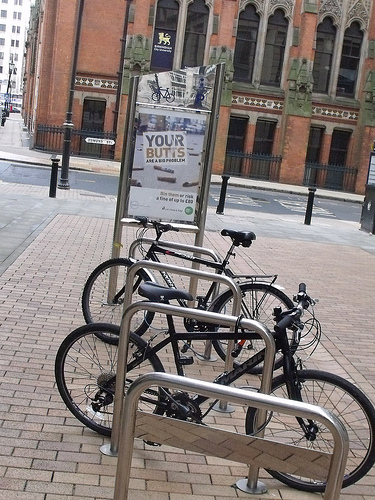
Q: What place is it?
A: It is a sidewalk.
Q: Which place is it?
A: It is a sidewalk.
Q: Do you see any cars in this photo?
A: No, there are no cars.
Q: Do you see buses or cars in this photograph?
A: No, there are no cars or buses.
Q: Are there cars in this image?
A: No, there are no cars.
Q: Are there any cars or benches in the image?
A: No, there are no cars or benches.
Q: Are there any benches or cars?
A: No, there are no cars or benches.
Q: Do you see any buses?
A: No, there are no buses.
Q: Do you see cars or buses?
A: No, there are no buses or cars.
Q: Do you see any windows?
A: Yes, there is a window.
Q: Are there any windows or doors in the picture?
A: Yes, there is a window.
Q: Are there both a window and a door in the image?
A: Yes, there are both a window and a door.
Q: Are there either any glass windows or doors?
A: Yes, there is a glass window.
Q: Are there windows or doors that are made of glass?
A: Yes, the window is made of glass.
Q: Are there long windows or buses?
A: Yes, there is a long window.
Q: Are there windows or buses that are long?
A: Yes, the window is long.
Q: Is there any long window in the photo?
A: Yes, there is a long window.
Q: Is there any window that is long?
A: Yes, there is a window that is long.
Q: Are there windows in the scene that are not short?
A: Yes, there is a long window.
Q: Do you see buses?
A: No, there are no buses.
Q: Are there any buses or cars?
A: No, there are no buses or cars.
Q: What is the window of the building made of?
A: The window is made of glass.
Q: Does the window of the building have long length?
A: Yes, the window is long.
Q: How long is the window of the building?
A: The window is long.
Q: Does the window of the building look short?
A: No, the window is long.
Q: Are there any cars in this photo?
A: No, there are no cars.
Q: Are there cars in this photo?
A: No, there are no cars.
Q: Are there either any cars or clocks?
A: No, there are no cars or clocks.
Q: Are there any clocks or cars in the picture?
A: No, there are no cars or clocks.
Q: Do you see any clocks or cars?
A: No, there are no cars or clocks.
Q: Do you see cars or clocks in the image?
A: No, there are no cars or clocks.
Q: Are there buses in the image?
A: No, there are no buses.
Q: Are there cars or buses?
A: No, there are no buses or cars.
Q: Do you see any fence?
A: Yes, there is a fence.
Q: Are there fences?
A: Yes, there is a fence.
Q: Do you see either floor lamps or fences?
A: Yes, there is a fence.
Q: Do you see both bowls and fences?
A: No, there is a fence but no bowls.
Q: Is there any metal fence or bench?
A: Yes, there is a metal fence.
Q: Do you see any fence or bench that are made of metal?
A: Yes, the fence is made of metal.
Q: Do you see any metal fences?
A: Yes, there is a metal fence.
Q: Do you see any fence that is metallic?
A: Yes, there is a fence that is metallic.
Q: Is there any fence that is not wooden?
A: Yes, there is a metallic fence.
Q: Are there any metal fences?
A: Yes, there is a fence that is made of metal.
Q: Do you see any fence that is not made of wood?
A: Yes, there is a fence that is made of metal.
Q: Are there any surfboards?
A: No, there are no surfboards.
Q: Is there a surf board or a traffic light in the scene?
A: No, there are no surfboards or traffic lights.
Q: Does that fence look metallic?
A: Yes, the fence is metallic.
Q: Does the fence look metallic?
A: Yes, the fence is metallic.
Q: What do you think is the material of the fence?
A: The fence is made of metal.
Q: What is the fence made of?
A: The fence is made of metal.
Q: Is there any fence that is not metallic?
A: No, there is a fence but it is metallic.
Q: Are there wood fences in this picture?
A: No, there is a fence but it is made of metal.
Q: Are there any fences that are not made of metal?
A: No, there is a fence but it is made of metal.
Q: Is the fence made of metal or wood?
A: The fence is made of metal.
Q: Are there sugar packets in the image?
A: No, there are no sugar packets.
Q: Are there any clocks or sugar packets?
A: No, there are no sugar packets or clocks.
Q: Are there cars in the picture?
A: No, there are no cars.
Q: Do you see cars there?
A: No, there are no cars.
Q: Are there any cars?
A: No, there are no cars.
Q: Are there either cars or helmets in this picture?
A: No, there are no cars or helmets.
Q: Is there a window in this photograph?
A: Yes, there is a window.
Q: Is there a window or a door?
A: Yes, there is a window.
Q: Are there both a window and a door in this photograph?
A: Yes, there are both a window and a door.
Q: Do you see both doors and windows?
A: Yes, there are both a window and a door.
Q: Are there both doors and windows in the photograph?
A: Yes, there are both a window and a door.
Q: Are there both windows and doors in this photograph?
A: Yes, there are both a window and a door.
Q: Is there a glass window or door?
A: Yes, there is a glass window.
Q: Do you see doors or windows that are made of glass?
A: Yes, the window is made of glass.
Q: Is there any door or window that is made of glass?
A: Yes, the window is made of glass.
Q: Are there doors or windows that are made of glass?
A: Yes, the window is made of glass.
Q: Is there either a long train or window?
A: Yes, there is a long window.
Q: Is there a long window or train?
A: Yes, there is a long window.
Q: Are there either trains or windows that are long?
A: Yes, the window is long.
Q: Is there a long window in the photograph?
A: Yes, there is a long window.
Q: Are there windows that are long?
A: Yes, there is a window that is long.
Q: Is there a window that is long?
A: Yes, there is a window that is long.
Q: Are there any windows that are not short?
A: Yes, there is a long window.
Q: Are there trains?
A: No, there are no trains.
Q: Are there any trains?
A: No, there are no trains.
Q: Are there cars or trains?
A: No, there are no trains or cars.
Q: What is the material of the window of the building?
A: The window is made of glass.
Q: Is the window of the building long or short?
A: The window is long.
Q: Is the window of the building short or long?
A: The window is long.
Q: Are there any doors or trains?
A: Yes, there is a door.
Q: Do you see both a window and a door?
A: Yes, there are both a door and a window.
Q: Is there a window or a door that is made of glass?
A: Yes, the door is made of glass.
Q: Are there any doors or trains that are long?
A: Yes, the door is long.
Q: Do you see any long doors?
A: Yes, there is a long door.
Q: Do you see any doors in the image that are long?
A: Yes, there is a door that is long.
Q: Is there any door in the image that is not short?
A: Yes, there is a long door.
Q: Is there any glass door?
A: Yes, there is a door that is made of glass.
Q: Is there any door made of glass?
A: Yes, there is a door that is made of glass.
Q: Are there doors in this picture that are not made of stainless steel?
A: Yes, there is a door that is made of glass.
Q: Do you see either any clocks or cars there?
A: No, there are no cars or clocks.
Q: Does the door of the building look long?
A: Yes, the door is long.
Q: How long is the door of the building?
A: The door is long.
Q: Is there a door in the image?
A: Yes, there is a door.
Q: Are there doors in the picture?
A: Yes, there is a door.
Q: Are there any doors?
A: Yes, there is a door.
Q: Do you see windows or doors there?
A: Yes, there is a door.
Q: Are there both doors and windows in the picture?
A: Yes, there are both a door and a window.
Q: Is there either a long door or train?
A: Yes, there is a long door.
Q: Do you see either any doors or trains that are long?
A: Yes, the door is long.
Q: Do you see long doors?
A: Yes, there is a long door.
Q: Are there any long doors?
A: Yes, there is a long door.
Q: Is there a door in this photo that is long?
A: Yes, there is a door that is long.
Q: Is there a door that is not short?
A: Yes, there is a long door.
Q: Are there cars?
A: No, there are no cars.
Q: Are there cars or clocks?
A: No, there are no cars or clocks.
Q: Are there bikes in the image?
A: Yes, there is a bike.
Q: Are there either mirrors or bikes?
A: Yes, there is a bike.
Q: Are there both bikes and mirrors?
A: No, there is a bike but no mirrors.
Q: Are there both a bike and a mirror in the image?
A: No, there is a bike but no mirrors.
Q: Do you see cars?
A: No, there are no cars.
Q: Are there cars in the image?
A: No, there are no cars.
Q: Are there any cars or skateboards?
A: No, there are no cars or skateboards.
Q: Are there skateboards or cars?
A: No, there are no cars or skateboards.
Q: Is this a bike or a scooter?
A: This is a bike.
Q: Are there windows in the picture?
A: Yes, there is a window.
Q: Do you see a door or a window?
A: Yes, there is a window.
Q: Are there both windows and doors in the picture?
A: Yes, there are both a window and a door.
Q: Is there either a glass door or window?
A: Yes, there is a glass window.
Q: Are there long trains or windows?
A: Yes, there is a long window.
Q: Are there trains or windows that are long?
A: Yes, the window is long.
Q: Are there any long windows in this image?
A: Yes, there is a long window.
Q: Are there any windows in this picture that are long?
A: Yes, there is a window that is long.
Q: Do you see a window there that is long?
A: Yes, there is a window that is long.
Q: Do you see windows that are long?
A: Yes, there is a window that is long.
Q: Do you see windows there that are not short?
A: Yes, there is a long window.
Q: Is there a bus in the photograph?
A: No, there are no buses.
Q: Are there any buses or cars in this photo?
A: No, there are no buses or cars.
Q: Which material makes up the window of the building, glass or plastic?
A: The window is made of glass.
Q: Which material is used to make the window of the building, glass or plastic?
A: The window is made of glass.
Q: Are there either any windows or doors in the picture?
A: Yes, there is a window.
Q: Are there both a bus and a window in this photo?
A: No, there is a window but no buses.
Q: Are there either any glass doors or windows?
A: Yes, there is a glass window.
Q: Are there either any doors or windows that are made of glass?
A: Yes, the window is made of glass.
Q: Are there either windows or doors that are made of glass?
A: Yes, the window is made of glass.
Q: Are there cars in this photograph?
A: No, there are no cars.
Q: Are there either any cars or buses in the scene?
A: No, there are no cars or buses.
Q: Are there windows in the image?
A: Yes, there is a window.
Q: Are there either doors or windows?
A: Yes, there is a window.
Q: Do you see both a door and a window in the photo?
A: Yes, there are both a window and a door.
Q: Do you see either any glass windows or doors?
A: Yes, there is a glass window.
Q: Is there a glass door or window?
A: Yes, there is a glass window.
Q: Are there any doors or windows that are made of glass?
A: Yes, the window is made of glass.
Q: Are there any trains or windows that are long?
A: Yes, the window is long.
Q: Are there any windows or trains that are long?
A: Yes, the window is long.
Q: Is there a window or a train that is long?
A: Yes, the window is long.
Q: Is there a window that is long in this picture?
A: Yes, there is a long window.